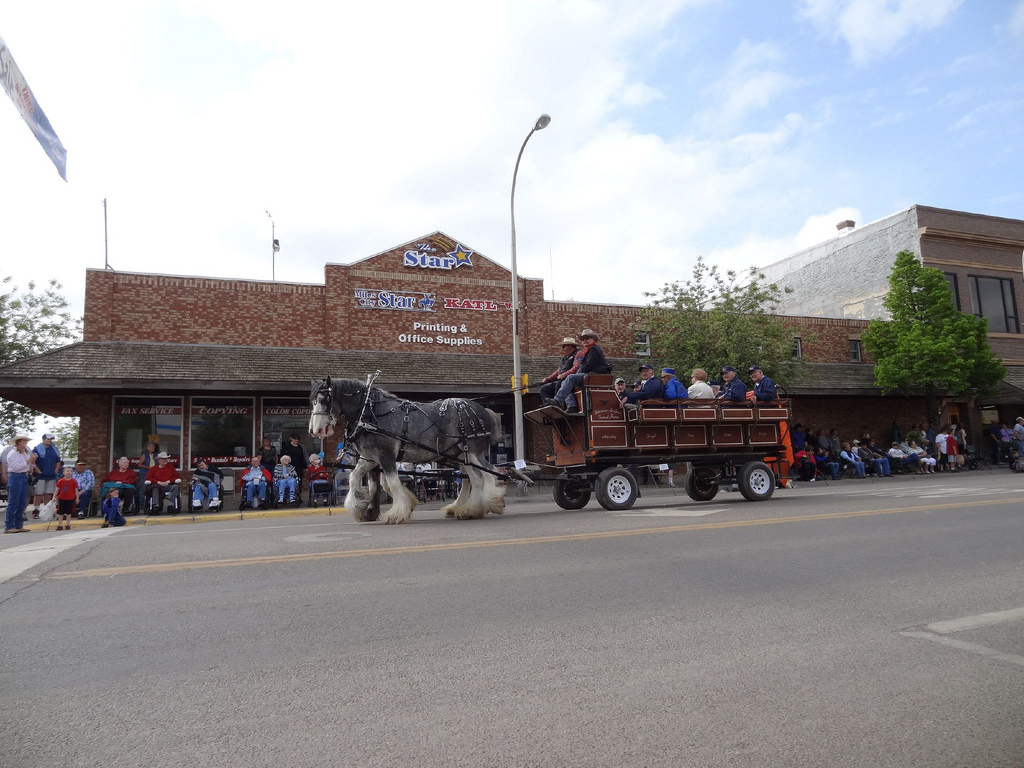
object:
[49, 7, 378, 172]
clouds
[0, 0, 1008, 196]
sky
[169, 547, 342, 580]
line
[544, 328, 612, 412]
people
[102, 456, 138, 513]
people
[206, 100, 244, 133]
clouds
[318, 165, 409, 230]
clouds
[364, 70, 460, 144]
clouds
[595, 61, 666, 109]
clouds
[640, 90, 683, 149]
clouds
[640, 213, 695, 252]
clouds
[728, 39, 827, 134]
clouds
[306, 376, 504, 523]
horse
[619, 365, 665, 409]
people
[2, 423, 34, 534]
person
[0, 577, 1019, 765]
land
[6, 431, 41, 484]
shirt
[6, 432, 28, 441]
cowboy hat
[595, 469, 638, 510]
tire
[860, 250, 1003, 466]
tree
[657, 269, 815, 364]
tree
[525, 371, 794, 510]
carriage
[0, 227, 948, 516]
building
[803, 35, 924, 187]
sky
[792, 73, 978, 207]
sky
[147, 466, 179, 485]
shirt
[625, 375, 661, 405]
shirt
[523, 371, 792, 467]
wagon